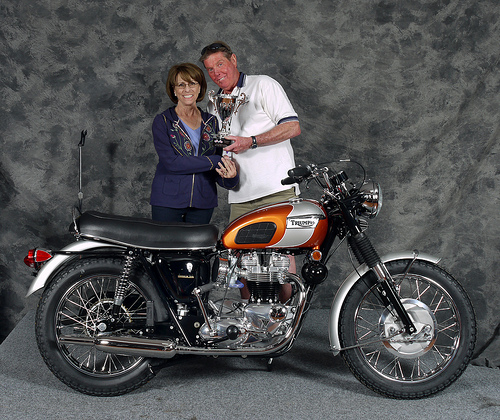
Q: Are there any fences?
A: No, there are no fences.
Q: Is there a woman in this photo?
A: Yes, there is a woman.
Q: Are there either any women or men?
A: Yes, there is a woman.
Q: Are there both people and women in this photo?
A: Yes, there are both a woman and a person.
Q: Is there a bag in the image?
A: No, there are no bags.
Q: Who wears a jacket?
A: The woman wears a jacket.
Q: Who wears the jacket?
A: The woman wears a jacket.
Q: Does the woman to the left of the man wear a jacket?
A: Yes, the woman wears a jacket.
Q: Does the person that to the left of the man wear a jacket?
A: Yes, the woman wears a jacket.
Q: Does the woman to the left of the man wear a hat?
A: No, the woman wears a jacket.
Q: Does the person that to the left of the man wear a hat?
A: No, the woman wears a jacket.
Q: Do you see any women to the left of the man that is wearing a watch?
A: Yes, there is a woman to the left of the man.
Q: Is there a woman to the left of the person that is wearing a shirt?
A: Yes, there is a woman to the left of the man.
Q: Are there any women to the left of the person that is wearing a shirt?
A: Yes, there is a woman to the left of the man.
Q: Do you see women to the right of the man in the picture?
A: No, the woman is to the left of the man.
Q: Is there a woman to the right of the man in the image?
A: No, the woman is to the left of the man.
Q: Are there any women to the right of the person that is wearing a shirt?
A: No, the woman is to the left of the man.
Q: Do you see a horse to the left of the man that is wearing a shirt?
A: No, there is a woman to the left of the man.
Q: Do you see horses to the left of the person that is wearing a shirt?
A: No, there is a woman to the left of the man.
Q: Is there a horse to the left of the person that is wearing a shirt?
A: No, there is a woman to the left of the man.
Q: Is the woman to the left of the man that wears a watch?
A: Yes, the woman is to the left of the man.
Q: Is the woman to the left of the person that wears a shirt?
A: Yes, the woman is to the left of the man.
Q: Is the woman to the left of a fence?
A: No, the woman is to the left of the man.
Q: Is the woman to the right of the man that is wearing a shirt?
A: No, the woman is to the left of the man.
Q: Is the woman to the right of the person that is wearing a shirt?
A: No, the woman is to the left of the man.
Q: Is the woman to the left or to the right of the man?
A: The woman is to the left of the man.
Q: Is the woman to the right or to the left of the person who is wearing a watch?
A: The woman is to the left of the man.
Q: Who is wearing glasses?
A: The woman is wearing glasses.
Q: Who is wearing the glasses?
A: The woman is wearing glasses.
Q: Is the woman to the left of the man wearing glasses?
A: Yes, the woman is wearing glasses.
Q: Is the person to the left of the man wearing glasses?
A: Yes, the woman is wearing glasses.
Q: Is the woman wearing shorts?
A: No, the woman is wearing glasses.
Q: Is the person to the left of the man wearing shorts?
A: No, the woman is wearing glasses.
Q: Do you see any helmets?
A: No, there are no helmets.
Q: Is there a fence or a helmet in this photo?
A: No, there are no helmets or fences.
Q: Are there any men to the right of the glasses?
A: Yes, there is a man to the right of the glasses.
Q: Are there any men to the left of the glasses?
A: No, the man is to the right of the glasses.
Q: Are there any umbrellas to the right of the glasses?
A: No, there is a man to the right of the glasses.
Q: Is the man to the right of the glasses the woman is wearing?
A: Yes, the man is to the right of the glasses.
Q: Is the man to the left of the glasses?
A: No, the man is to the right of the glasses.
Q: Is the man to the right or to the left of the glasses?
A: The man is to the right of the glasses.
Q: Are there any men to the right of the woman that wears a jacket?
A: Yes, there is a man to the right of the woman.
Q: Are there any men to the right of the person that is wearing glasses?
A: Yes, there is a man to the right of the woman.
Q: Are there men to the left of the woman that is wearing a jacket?
A: No, the man is to the right of the woman.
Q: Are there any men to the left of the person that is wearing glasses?
A: No, the man is to the right of the woman.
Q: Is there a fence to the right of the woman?
A: No, there is a man to the right of the woman.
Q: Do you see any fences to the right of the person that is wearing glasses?
A: No, there is a man to the right of the woman.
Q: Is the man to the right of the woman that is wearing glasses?
A: Yes, the man is to the right of the woman.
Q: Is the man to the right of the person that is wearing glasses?
A: Yes, the man is to the right of the woman.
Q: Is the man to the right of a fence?
A: No, the man is to the right of the woman.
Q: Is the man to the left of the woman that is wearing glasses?
A: No, the man is to the right of the woman.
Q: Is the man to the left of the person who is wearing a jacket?
A: No, the man is to the right of the woman.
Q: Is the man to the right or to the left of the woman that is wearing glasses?
A: The man is to the right of the woman.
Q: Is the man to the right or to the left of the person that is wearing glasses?
A: The man is to the right of the woman.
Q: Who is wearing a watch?
A: The man is wearing a watch.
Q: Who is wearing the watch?
A: The man is wearing a watch.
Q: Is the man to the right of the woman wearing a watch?
A: Yes, the man is wearing a watch.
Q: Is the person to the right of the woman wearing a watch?
A: Yes, the man is wearing a watch.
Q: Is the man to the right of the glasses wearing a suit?
A: No, the man is wearing a watch.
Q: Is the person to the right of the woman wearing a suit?
A: No, the man is wearing a watch.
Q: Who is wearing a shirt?
A: The man is wearing a shirt.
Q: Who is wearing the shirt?
A: The man is wearing a shirt.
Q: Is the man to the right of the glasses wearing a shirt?
A: Yes, the man is wearing a shirt.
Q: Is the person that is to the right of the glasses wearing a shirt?
A: Yes, the man is wearing a shirt.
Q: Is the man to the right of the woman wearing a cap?
A: No, the man is wearing a shirt.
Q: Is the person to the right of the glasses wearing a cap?
A: No, the man is wearing a shirt.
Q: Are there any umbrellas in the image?
A: No, there are no umbrellas.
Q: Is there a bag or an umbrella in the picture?
A: No, there are no umbrellas or bags.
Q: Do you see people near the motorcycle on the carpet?
A: Yes, there are people near the motorbike.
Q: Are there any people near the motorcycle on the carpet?
A: Yes, there are people near the motorbike.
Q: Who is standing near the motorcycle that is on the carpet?
A: The people are standing near the motorcycle.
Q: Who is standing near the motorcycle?
A: The people are standing near the motorcycle.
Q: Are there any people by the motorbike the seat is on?
A: Yes, there are people by the motorbike.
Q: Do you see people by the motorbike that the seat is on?
A: Yes, there are people by the motorbike.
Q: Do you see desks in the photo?
A: No, there are no desks.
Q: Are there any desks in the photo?
A: No, there are no desks.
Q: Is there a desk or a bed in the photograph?
A: No, there are no desks or beds.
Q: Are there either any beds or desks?
A: No, there are no desks or beds.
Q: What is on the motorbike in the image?
A: The seat is on the motorbike.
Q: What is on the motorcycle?
A: The seat is on the motorbike.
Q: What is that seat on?
A: The seat is on the motorcycle.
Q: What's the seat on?
A: The seat is on the motorcycle.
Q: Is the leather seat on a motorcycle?
A: Yes, the seat is on a motorcycle.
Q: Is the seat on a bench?
A: No, the seat is on a motorcycle.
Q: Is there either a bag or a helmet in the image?
A: No, there are no helmets or bags.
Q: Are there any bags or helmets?
A: No, there are no helmets or bags.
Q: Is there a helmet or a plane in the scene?
A: No, there are no helmets or airplanes.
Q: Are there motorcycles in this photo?
A: Yes, there is a motorcycle.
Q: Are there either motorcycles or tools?
A: Yes, there is a motorcycle.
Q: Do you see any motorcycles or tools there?
A: Yes, there is a motorcycle.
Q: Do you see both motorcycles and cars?
A: No, there is a motorcycle but no cars.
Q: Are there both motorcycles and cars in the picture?
A: No, there is a motorcycle but no cars.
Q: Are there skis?
A: No, there are no skis.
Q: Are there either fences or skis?
A: No, there are no skis or fences.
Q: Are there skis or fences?
A: No, there are no skis or fences.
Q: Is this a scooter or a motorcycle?
A: This is a motorcycle.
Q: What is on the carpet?
A: The motorbike is on the carpet.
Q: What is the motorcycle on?
A: The motorcycle is on the carpet.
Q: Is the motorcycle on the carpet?
A: Yes, the motorcycle is on the carpet.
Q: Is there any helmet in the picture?
A: No, there are no helmets.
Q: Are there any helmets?
A: No, there are no helmets.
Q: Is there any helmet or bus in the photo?
A: No, there are no helmets or buses.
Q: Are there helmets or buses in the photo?
A: No, there are no helmets or buses.